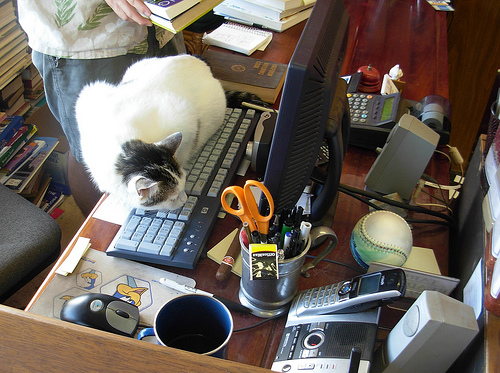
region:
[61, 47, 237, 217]
A CAT ON THE DESK TOP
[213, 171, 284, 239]
A PAIR OF ORANGE SCISSORS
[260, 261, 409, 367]
A LAND LINE PHONE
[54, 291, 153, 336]
A GRAY AND BLACK MOUSE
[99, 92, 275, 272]
A COMPUTER KEYBOARD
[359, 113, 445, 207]
A COMPUTER SPEAKER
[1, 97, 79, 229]
A PILE OF BOOKS ON THE FLOOR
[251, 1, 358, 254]
A FLAT SCREEN MONITOR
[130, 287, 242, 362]
A BLUE COFFEE CUP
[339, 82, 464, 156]
A DESK TOP CALCULATOR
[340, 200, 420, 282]
ball on a desk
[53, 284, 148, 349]
computer mouse on a desk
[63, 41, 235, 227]
cat on a computer keyboard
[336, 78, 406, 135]
calculator on a desk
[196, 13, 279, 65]
notebook on a desk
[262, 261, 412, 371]
telephone on a desk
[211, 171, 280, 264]
scissors in a mug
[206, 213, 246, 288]
cigar on a desk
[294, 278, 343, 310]
buttons on a telephone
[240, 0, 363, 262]
computer monitor on a desk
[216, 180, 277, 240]
pair of scissors with orange handles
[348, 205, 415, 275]
softball on a desk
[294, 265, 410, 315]
cordless phone on the base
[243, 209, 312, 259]
pens in a mug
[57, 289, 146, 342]
black and grey computer mouse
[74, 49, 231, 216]
cat on a keyboard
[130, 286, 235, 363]
blue colored coffee mug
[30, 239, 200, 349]
cartoon mouse pad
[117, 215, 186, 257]
number pad on a keyboard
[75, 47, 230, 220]
cat sitting on edge of desk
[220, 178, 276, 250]
orange handle of scissors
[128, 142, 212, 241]
cat head over keyboard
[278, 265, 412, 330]
cordless phone and cradle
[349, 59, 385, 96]
red bell on desk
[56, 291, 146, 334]
computer mouse on pad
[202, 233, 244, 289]
cigar on yellow pad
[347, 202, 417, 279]
white softball on desk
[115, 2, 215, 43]
hand holding two books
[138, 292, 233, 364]
blue coffee cup on desk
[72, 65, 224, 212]
black and white cat on keyboard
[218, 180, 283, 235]
scissors with orange handles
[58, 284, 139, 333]
black and gray mouse on pad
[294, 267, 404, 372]
silver and black cordless phone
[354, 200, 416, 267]
white baseball on desk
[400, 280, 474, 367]
gray speaker on desk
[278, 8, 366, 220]
black computer monitor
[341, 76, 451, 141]
black adding machine on desk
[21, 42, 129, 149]
person wearing gray pants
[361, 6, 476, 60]
dark brown wooden floor